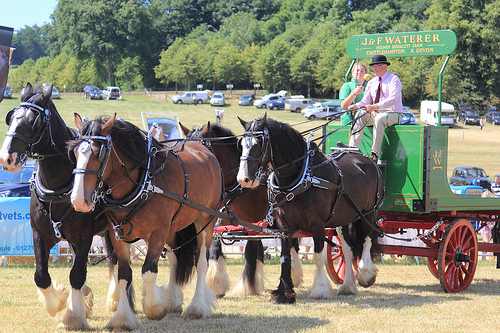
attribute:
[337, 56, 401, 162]
person — present, driving, sitting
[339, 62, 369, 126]
person — present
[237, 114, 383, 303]
horse — present, brown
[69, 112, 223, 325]
horse — present, light brown, in front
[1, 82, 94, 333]
horse — present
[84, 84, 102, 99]
car — present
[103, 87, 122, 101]
car — present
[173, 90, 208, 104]
car — present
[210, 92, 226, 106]
car — present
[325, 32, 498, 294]
carriage — green, red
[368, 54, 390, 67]
hat — black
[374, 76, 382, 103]
tie — red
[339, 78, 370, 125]
shirt — green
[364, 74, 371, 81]
microphone top — yellow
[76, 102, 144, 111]
grass — green, brown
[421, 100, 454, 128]
camper — white, parked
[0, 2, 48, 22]
sky — blue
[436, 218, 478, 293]
wheel — in front, on left, red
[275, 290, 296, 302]
hoof — brown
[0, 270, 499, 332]
ground — dead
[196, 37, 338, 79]
leaves — green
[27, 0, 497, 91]
trees — on side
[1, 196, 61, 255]
banner — present